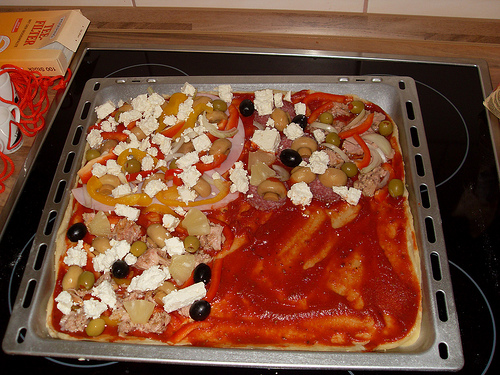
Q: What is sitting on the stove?
A: A pizza.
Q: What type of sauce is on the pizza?
A: Tomato.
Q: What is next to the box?
A: The long red tangled string.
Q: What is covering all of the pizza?
A: The red tomato sauce.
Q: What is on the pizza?
A: The ricotta cheese.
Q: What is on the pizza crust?
A: The red pizza sauce.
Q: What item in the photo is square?
A: The pizza pan.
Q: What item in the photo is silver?
A: The pizza pan.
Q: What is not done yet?
A: The pizza.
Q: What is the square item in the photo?
A: The uncooked pizza.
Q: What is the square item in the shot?
A: The pizza pan.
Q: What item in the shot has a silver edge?
A: The black stove top.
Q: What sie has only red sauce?
A: The bottom right.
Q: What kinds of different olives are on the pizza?
A: 3 kinds.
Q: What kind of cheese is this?
A: Feta cheese.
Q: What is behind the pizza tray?
A: A wooden wall trim.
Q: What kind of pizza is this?
A: A home made pizza.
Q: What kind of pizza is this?
A: Supreme.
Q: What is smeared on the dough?
A: Red sauce.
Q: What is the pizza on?
A: A thin silver tray.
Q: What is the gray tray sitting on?
A: The stove top.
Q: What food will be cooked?
A: The pizza.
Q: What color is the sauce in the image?
A: Red.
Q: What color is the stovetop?
A: Black.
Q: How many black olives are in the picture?
A: Seven.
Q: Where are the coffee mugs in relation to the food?
A: Left.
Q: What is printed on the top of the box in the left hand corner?
A: Tee Filter.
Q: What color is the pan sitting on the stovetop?
A: Silver.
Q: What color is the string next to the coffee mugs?
A: Orange.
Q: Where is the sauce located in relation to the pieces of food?
A: Underneath.